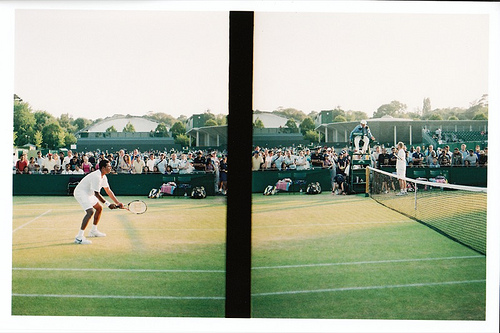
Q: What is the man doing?
A: Playing tennis.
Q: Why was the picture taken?
A: To capture the man.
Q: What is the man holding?
A: A tennis racket.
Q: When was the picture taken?
A: During a tennis match.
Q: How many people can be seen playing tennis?
A: One.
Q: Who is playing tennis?
A: A man.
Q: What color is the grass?
A: Green.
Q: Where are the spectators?
A: On the sidelines.